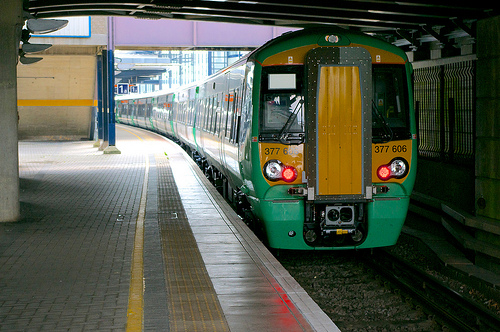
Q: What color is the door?
A: Yellow.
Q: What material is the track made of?
A: Steel.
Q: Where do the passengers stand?
A: Loading zone.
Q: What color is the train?
A: Green and yellow.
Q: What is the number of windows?
A: Two.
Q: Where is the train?
A: Station.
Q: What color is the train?
A: Green and yellow.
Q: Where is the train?
A: In the station.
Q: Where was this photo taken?
A: Train station.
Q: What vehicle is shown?
A: Train.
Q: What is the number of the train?
A: 377606.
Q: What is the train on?
A: Track.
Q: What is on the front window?
A: Wipers.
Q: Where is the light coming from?
A: Headlights.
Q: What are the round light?
A: Headlights.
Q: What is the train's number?
A: 377 606.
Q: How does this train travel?
A: On tracks.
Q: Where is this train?
A: At the station.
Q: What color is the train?
A: Green and yellow.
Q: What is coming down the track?
A: A train.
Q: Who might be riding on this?
A: Commuters.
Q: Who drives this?
A: A conductor.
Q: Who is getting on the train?
A: Nobody.